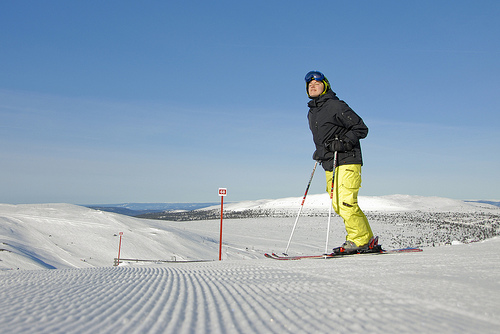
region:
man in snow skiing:
[283, 70, 393, 252]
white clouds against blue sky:
[35, 6, 84, 55]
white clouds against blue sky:
[17, 64, 111, 136]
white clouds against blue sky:
[41, 122, 122, 184]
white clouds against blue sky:
[125, 117, 215, 194]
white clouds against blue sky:
[221, 126, 302, 188]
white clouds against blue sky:
[97, 27, 298, 125]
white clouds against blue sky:
[324, 12, 425, 52]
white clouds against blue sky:
[395, 49, 459, 113]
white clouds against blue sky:
[376, 51, 466, 147]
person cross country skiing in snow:
[285, 72, 383, 243]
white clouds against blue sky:
[14, 18, 116, 85]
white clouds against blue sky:
[22, 53, 76, 110]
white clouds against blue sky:
[22, 121, 86, 171]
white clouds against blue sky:
[107, 119, 167, 166]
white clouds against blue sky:
[172, 116, 272, 183]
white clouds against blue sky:
[368, 119, 466, 174]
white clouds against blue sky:
[362, 29, 440, 99]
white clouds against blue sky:
[84, 28, 159, 88]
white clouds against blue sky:
[205, 45, 293, 106]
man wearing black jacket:
[297, 105, 357, 158]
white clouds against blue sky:
[15, 83, 82, 130]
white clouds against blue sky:
[30, 155, 80, 199]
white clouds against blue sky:
[88, 128, 180, 188]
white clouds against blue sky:
[124, 16, 186, 54]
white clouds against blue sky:
[164, 63, 225, 111]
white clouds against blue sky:
[168, 133, 266, 168]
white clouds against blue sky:
[247, 15, 321, 52]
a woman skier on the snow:
[258, 55, 428, 300]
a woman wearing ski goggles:
[298, 65, 330, 102]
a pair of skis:
[263, 241, 428, 261]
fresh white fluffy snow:
[16, 272, 498, 332]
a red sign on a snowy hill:
[209, 183, 234, 261]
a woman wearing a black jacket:
[291, 70, 398, 262]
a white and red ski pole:
[286, 147, 319, 254]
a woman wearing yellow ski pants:
[296, 65, 397, 272]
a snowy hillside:
[2, 190, 146, 268]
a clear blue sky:
[1, 0, 299, 177]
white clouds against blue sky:
[17, 6, 54, 47]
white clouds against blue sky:
[15, 96, 143, 130]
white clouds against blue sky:
[135, 12, 235, 82]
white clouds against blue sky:
[138, 103, 232, 138]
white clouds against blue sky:
[245, 45, 296, 117]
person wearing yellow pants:
[311, 162, 375, 264]